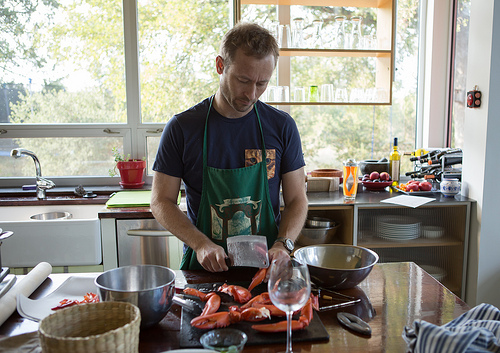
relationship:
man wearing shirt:
[149, 24, 309, 273] [150, 93, 305, 241]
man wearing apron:
[149, 24, 309, 273] [181, 93, 277, 269]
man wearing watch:
[149, 24, 309, 273] [273, 237, 295, 252]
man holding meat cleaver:
[149, 24, 309, 273] [223, 233, 268, 268]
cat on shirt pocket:
[243, 149, 276, 179] [241, 144, 278, 184]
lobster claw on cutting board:
[186, 283, 218, 315] [181, 273, 330, 347]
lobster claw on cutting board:
[191, 305, 270, 330] [181, 273, 330, 347]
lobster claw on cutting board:
[251, 298, 314, 333] [181, 273, 330, 347]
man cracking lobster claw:
[149, 24, 309, 273] [249, 266, 267, 293]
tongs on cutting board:
[174, 291, 235, 313] [181, 273, 330, 347]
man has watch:
[149, 24, 309, 273] [273, 237, 295, 252]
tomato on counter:
[420, 181, 433, 191] [100, 185, 482, 217]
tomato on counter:
[406, 183, 418, 192] [100, 185, 482, 217]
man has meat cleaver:
[149, 24, 309, 273] [223, 233, 268, 268]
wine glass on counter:
[266, 255, 311, 352] [0, 259, 499, 351]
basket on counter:
[40, 299, 144, 352] [0, 259, 499, 351]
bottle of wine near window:
[390, 134, 402, 187] [1, 0, 420, 179]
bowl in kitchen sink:
[29, 206, 72, 220] [0, 206, 104, 267]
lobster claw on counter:
[186, 283, 218, 315] [0, 259, 499, 351]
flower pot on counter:
[116, 157, 147, 187] [100, 185, 482, 217]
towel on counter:
[400, 302, 499, 352] [0, 259, 499, 351]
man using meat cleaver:
[149, 24, 309, 273] [223, 233, 268, 268]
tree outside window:
[2, 0, 223, 175] [1, 0, 420, 179]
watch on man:
[273, 237, 295, 252] [149, 24, 309, 273]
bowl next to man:
[294, 245, 381, 289] [149, 24, 309, 273]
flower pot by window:
[116, 157, 147, 187] [1, 0, 420, 179]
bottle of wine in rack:
[426, 154, 463, 167] [406, 148, 461, 186]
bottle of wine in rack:
[423, 171, 458, 182] [406, 148, 461, 186]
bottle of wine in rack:
[409, 147, 440, 165] [406, 148, 461, 186]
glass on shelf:
[351, 11, 363, 50] [237, 0, 391, 52]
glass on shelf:
[332, 15, 346, 48] [237, 0, 391, 52]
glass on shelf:
[291, 17, 307, 49] [237, 0, 391, 52]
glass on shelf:
[277, 23, 292, 48] [237, 0, 391, 52]